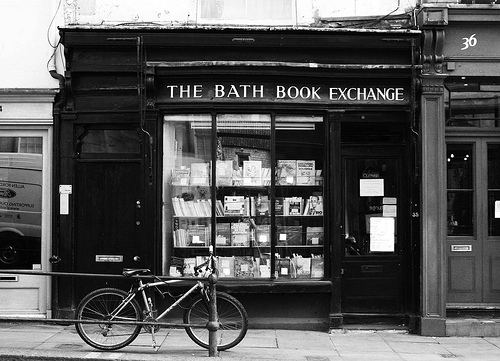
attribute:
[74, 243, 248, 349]
bike — parked, silver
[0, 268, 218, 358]
railing — metal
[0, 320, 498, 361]
sidewalk — partial, gray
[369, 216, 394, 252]
sign — white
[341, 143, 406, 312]
door — black, partial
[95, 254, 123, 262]
mailbox — metal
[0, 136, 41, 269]
window — partial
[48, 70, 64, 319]
pipe — partial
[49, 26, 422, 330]
store — black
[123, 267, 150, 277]
seat — black, leather